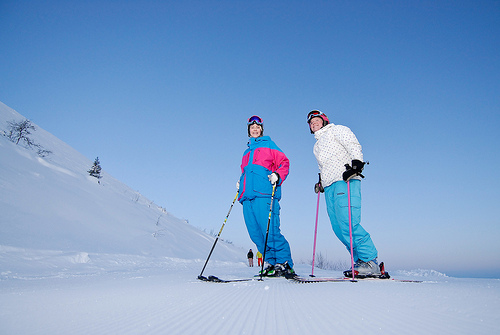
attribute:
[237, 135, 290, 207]
blue jacket — down-filled, warm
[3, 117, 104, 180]
trees — snowy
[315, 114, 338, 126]
band — red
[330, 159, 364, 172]
gloves — black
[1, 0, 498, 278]
sky — blue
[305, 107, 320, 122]
goggles — sporty, protective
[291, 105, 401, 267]
woman — rubberized, unbreakable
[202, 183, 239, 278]
pole — black, white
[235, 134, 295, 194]
jacket — blue, pink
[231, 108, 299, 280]
female — happy, exhilerated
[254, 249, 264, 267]
person — distant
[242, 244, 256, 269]
person — distant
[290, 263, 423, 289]
skis — long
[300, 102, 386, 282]
woman — nylon, down-filled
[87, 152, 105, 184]
tree — small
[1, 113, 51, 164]
tree — small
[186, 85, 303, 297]
skier — female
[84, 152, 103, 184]
pine tree — tiny, green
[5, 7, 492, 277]
skies — breathtaking, serene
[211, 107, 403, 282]
women — skiing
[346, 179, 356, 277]
ski pole — fuschia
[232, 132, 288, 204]
coat — blue, pink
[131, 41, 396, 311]
skiers — female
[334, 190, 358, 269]
poles — skinny, strong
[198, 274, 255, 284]
snow ski — durable, ladies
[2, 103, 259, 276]
hill — sloped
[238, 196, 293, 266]
ski pants — blue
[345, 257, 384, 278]
ski boots — gray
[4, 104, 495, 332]
snow — pure, crystal, white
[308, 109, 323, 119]
goggles — white